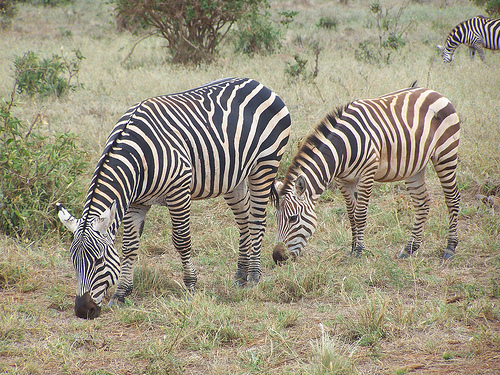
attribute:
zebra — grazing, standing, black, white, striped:
[285, 96, 467, 265]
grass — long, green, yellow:
[196, 310, 284, 352]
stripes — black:
[168, 98, 207, 194]